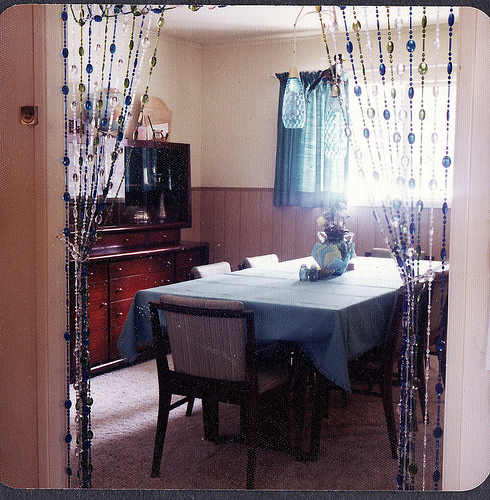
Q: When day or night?
A: Daytime.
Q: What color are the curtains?
A: Blue.